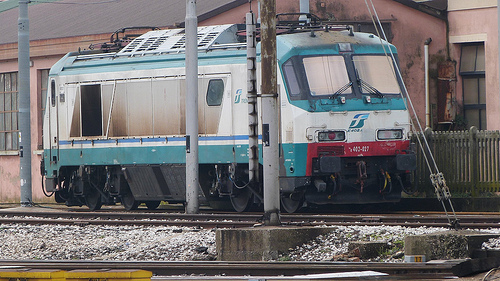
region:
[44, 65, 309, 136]
white stripe on the train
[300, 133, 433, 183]
red on the front of the train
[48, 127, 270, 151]
blue stripe on the train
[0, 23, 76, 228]
pink is on the building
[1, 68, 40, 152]
window panes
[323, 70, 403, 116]
windshield wipers on the train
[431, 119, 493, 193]
fence next to train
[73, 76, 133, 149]
window open on the train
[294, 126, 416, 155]
lights on the train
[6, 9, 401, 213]
poles on front of the train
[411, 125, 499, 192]
a small wooden fence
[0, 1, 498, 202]
A small red building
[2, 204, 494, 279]
some train tracks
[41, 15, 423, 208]
a white and blue train engine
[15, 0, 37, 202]
a large metal pole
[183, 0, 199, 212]
a large metal pole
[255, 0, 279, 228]
a large metal pole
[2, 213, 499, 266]
some gravel on the ground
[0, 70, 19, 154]
a window on a building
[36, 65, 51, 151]
a window on a building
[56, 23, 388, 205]
this is a train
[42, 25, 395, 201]
the train is short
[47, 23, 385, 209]
the train is motionless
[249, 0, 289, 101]
this is a pole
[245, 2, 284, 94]
the pole is rusty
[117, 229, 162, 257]
these are small stones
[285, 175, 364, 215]
this is the front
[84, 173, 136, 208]
these are the wheels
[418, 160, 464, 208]
this is a line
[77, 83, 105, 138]
the window is open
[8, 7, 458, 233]
the scene is at a railway stopway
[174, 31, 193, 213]
the posts are metalic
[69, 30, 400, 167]
the train is blue in color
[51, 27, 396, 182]
the train has white stripes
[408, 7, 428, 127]
the building is dull pink in color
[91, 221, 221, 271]
the railway is rough rugged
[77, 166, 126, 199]
the train wheels are black in color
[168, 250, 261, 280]
the railway is metallic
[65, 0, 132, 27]
the buiding roof is grey in color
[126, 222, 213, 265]
the railfloor is stoney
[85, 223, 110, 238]
this is the ground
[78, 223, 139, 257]
the ground has pebbles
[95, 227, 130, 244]
the pebbles are grey in color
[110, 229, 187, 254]
the pebbles are small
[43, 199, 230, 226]
this is a railway line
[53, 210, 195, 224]
the line is long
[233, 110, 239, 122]
the train is white in color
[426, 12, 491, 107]
this is a building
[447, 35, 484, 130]
this is a window